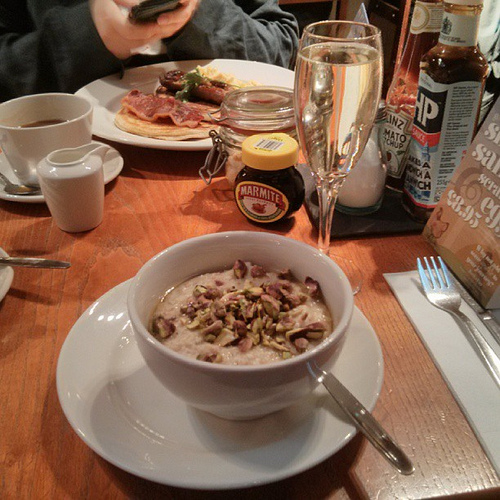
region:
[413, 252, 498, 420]
a fork on the table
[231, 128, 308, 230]
one bottle of marmite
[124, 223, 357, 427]
one bowl of soup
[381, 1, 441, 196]
one bottle of ketchup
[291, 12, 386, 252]
a long stem wine glass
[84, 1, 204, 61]
holding cellphone in hands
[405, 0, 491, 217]
a bottle of steak sauce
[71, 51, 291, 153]
a plate of food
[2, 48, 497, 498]
A BROWN WOODEN TABLE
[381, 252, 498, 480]
a white napkin on table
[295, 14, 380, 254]
a clear stemmed glass of wine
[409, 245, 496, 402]
a silver fork utensil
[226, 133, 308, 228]
a small jar of marmite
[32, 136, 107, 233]
a white porcelain syrup pitcher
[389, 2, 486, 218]
a bottle of red sauce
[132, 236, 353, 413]
a bowl of cereal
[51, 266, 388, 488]
a white saucer dish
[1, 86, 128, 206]
a white cup of coffee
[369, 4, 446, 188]
a bottle of ketchup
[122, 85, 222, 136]
a slice of bacon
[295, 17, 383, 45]
Top of wine glass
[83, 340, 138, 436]
White plate on table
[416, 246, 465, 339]
Silver fork on napkin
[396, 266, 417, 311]
white napkin under fork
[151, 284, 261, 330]
Food in white bowl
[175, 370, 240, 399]
White bowl on plate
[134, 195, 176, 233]
Wooden top of table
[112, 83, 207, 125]
Bacon on top of egg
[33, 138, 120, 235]
Sugar holder on table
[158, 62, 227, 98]
Sausage on top of egg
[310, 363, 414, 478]
a silver handle of a utensil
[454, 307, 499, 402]
a silver handle of a utensil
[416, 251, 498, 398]
a metal fork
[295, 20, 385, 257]
a full champagne glass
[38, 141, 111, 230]
a small white creamer dish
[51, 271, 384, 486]
a small white dish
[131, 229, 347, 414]
a small white bowl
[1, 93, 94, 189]
a white coffee mug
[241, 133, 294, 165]
a yellow plastic dish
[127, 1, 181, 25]
a black cell phone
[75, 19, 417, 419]
two place setting with lunch food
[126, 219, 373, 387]
bowl of soup on round white plate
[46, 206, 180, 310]
dishes are on wooden table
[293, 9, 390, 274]
glass of wine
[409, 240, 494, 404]
knife and fork on white napkin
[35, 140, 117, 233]
tiny pitcher of cream for coffee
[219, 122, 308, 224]
small jar of Marmite on table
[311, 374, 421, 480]
back of utensil resting on plate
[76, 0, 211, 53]
hands holding a cell phone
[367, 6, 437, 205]
bottle of ketchup